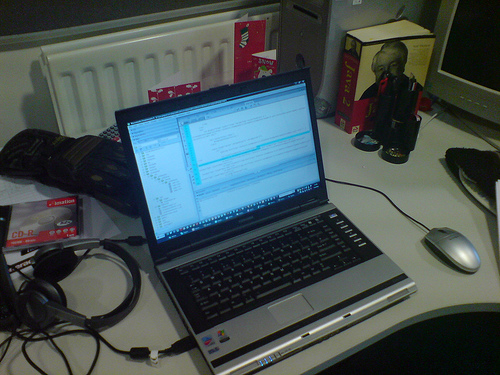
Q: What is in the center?
A: Older laptop.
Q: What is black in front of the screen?
A: Keyboard.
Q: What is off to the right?
A: Crt monitor.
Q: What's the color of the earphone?
A: Black.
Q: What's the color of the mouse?
A: Silver.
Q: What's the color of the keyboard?
A: Black.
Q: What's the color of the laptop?
A: Silver.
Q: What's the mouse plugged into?
A: Laptop.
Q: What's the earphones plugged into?
A: Laptop.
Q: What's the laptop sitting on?
A: Desk.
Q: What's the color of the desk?
A: White.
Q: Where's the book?
A: Desk.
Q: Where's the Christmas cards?
A: Desk.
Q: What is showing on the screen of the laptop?
A: A document.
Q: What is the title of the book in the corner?
A: Java 2.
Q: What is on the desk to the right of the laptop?
A: A mouse.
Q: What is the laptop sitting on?
A: The desk.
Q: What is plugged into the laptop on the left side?
A: Headphones.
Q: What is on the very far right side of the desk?
A: A turned off monitor.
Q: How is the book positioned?
A: It is standing on end.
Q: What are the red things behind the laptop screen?
A: Cards.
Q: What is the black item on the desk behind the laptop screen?
A: A glove.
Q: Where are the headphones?
A: Next to the computer.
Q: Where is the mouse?
A: On the desk.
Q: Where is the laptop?
A: On the desk.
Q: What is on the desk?
A: Mouse.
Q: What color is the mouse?
A: Gray.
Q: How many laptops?
A: 1.